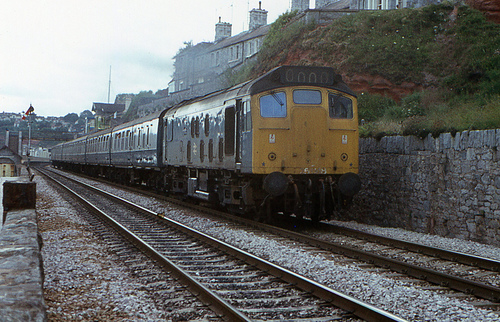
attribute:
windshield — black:
[253, 89, 285, 124]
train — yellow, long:
[163, 70, 361, 200]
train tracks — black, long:
[105, 203, 207, 263]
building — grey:
[214, 40, 249, 62]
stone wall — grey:
[404, 136, 464, 178]